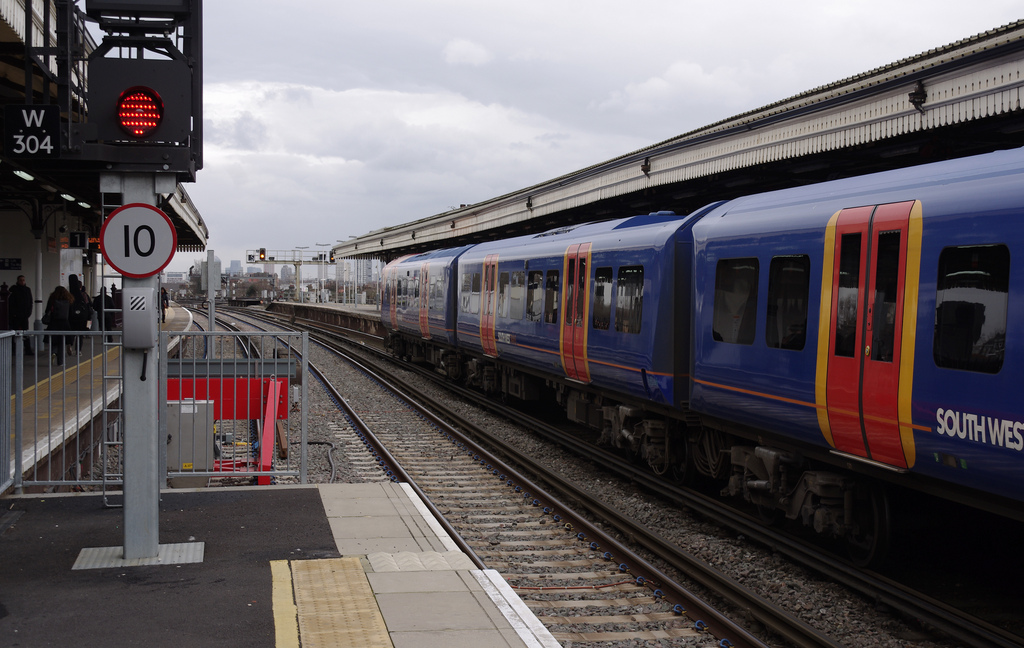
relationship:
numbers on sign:
[110, 195, 180, 301] [78, 143, 279, 634]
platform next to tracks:
[62, 253, 428, 645] [222, 299, 644, 643]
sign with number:
[88, 160, 214, 344] [90, 195, 194, 297]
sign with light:
[77, 35, 240, 329] [92, 53, 240, 188]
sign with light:
[41, 40, 255, 457] [32, 31, 551, 466]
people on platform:
[16, 266, 174, 446] [50, 331, 256, 502]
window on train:
[917, 208, 995, 327] [621, 223, 948, 567]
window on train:
[780, 186, 884, 385] [566, 255, 839, 390]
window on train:
[647, 247, 756, 382] [519, 199, 921, 454]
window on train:
[564, 251, 705, 385] [582, 245, 859, 433]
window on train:
[571, 243, 638, 391] [448, 227, 729, 415]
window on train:
[583, 257, 652, 341] [418, 236, 708, 418]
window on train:
[398, 219, 559, 412] [573, 158, 822, 521]